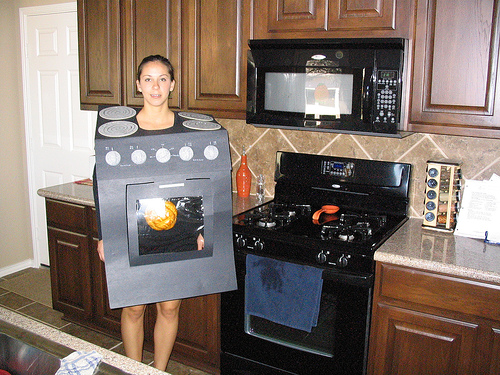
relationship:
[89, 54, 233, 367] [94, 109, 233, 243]
woman wearing costume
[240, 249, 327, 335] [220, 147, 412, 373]
towel on stove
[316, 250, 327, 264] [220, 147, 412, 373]
handle on stove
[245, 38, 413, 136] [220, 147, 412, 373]
microwave above stove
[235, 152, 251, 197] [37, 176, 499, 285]
bottle on counter-top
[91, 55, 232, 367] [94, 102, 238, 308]
woman wearing costume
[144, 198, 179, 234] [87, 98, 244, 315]
bun on costume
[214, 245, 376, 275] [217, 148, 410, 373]
handle of oven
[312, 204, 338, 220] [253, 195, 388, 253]
spoon on stove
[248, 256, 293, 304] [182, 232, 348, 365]
stain on towel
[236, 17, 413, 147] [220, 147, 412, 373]
microwave over stove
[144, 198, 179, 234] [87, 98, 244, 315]
bun on front of stove costume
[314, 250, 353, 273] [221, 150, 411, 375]
handle on oven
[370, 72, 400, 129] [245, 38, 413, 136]
control panel on microwave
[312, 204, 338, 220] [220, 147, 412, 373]
spoon on stove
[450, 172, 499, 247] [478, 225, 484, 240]
papers held by holder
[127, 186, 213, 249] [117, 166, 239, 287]
panel on door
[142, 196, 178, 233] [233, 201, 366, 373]
bun in oven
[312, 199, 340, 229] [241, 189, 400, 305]
spoon on stove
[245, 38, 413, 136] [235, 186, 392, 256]
microwave over range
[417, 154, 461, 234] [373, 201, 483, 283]
spicerack on counter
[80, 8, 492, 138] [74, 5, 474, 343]
cabinets against wall